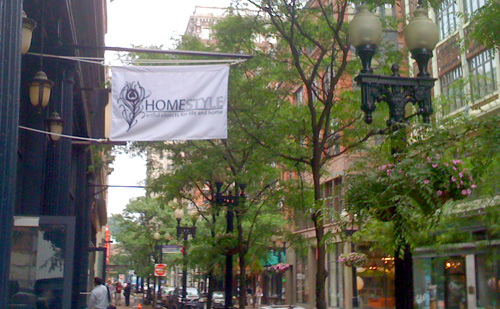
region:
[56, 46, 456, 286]
pedestrian walkway between builings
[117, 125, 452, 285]
trees growing in middle of walkway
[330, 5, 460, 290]
black lamppost with two bulbs on top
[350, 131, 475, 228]
lush hanging basket with pink flowers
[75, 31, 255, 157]
white banner hanging over walkway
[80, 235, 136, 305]
person entering open door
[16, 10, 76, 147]
hanging light fixtures in front of store front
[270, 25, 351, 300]
thin trunk with thin angled branches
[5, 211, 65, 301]
glass door reflecting street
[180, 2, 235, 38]
corner of building over tree top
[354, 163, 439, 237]
some green leaves of a tree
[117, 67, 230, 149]
a white hanged banner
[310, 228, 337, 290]
stem of a tree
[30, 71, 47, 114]
part of a street lamp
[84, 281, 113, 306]
a person in a white shirt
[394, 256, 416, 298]
stem of a black pole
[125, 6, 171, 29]
part of a white sky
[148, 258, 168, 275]
part of a red sign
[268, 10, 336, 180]
branches of a tree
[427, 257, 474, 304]
windows of a stall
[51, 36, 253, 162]
homestyle flag on building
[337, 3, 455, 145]
iron lamp on street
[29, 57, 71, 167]
street lamps on building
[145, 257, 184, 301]
do not enter sign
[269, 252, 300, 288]
pink flowers on street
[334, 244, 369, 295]
more pink flower in basket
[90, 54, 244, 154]
homestyle flag with white background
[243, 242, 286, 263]
green awning on building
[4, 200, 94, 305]
mirror on building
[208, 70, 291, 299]
tall green tree in front of buildings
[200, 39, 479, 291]
row of houses with trees in front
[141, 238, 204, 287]
do not enter sign near street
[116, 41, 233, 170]
welcoming flag says 'Homestyle'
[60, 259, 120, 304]
man entering building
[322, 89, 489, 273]
hanging basket of flowers decorates street light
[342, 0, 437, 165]
decorative double street light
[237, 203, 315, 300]
pink awning on storefront entrance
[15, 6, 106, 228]
lights on the building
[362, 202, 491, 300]
storefront with light in window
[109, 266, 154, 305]
people walking on the sidewalk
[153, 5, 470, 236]
Black light posts line the street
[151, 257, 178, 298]
Red and white sign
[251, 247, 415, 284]
Hanging flowering baskets on the side of street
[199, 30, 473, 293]
Tall buildings line the street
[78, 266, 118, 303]
Man entering building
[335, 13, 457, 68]
Lights on tall posts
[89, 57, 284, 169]
White banner with writing on it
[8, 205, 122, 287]
Open door to building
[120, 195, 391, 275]
Tall trees next to posts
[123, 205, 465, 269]
Leaves are green on trees